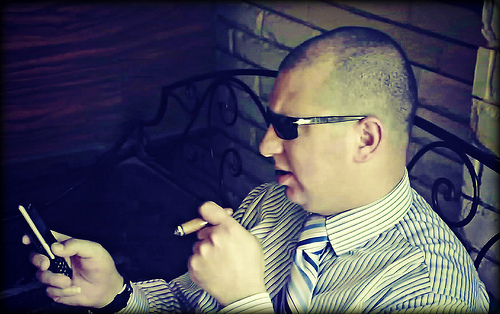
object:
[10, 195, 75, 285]
cellphone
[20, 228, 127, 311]
hand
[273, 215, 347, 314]
tie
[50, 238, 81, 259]
thumb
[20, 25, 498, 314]
man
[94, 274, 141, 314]
watch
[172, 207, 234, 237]
cigar